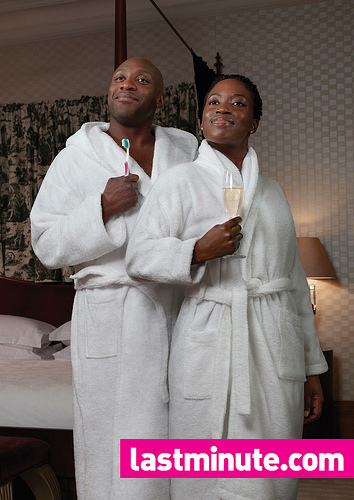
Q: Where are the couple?
A: In a hotel room.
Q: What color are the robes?
A: White.